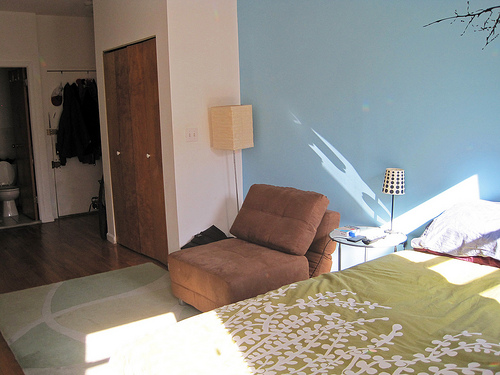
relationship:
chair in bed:
[165, 183, 336, 312] [101, 196, 495, 373]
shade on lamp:
[207, 101, 255, 151] [207, 100, 256, 227]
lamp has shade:
[207, 102, 254, 214] [205, 100, 260, 155]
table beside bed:
[329, 224, 408, 271] [108, 249, 497, 374]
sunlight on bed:
[335, 175, 498, 284] [101, 196, 495, 373]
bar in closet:
[42, 63, 94, 75] [36, 0, 106, 223]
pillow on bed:
[431, 191, 491, 256] [55, 188, 498, 373]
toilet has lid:
[1, 158, 23, 224] [2, 159, 14, 189]